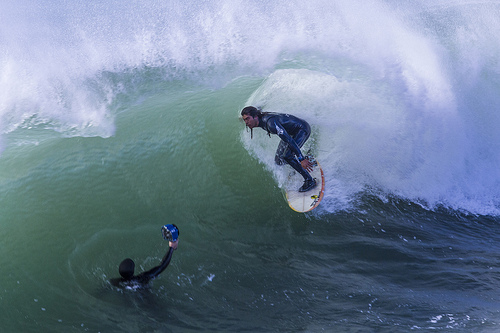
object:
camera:
[159, 223, 185, 241]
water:
[1, 71, 185, 194]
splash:
[115, 7, 210, 71]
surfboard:
[283, 159, 327, 214]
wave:
[2, 1, 499, 220]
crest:
[2, 29, 500, 105]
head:
[119, 256, 136, 279]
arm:
[141, 241, 179, 285]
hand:
[298, 157, 313, 171]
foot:
[295, 178, 323, 193]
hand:
[168, 239, 181, 247]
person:
[241, 107, 316, 194]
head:
[240, 105, 260, 129]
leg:
[284, 134, 320, 193]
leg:
[274, 138, 293, 166]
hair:
[118, 256, 137, 279]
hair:
[240, 105, 271, 138]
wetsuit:
[110, 246, 179, 288]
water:
[236, 237, 498, 331]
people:
[110, 223, 180, 293]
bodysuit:
[258, 111, 317, 191]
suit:
[265, 110, 318, 192]